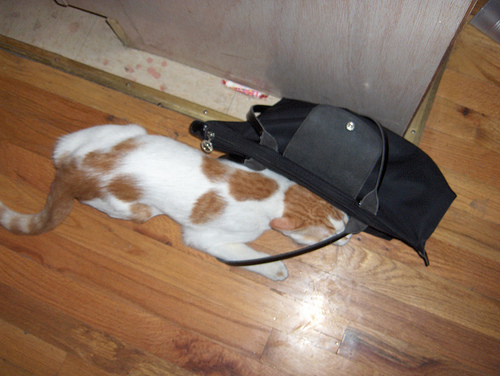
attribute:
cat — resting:
[21, 96, 373, 315]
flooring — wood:
[0, 2, 498, 373]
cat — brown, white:
[21, 87, 383, 303]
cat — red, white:
[2, 74, 458, 361]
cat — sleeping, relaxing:
[5, 98, 388, 304]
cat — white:
[0, 111, 362, 284]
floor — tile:
[42, 72, 499, 351]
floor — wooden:
[113, 282, 240, 361]